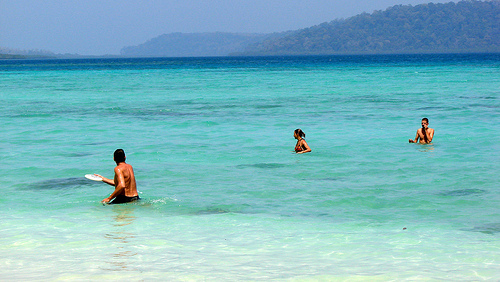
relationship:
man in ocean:
[85, 149, 139, 207] [180, 55, 266, 146]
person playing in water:
[293, 128, 312, 153] [4, 61, 477, 256]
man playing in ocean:
[85, 149, 139, 207] [0, 64, 500, 280]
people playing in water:
[98, 106, 455, 208] [323, 65, 372, 98]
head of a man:
[114, 147, 125, 165] [410, 116, 432, 142]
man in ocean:
[85, 149, 139, 207] [1, 52, 498, 280]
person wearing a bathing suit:
[293, 128, 312, 153] [292, 137, 305, 152]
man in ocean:
[85, 149, 139, 207] [0, 64, 500, 280]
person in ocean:
[290, 125, 312, 154] [0, 64, 500, 280]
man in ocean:
[409, 117, 435, 145] [0, 64, 500, 280]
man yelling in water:
[398, 108, 439, 152] [319, 141, 483, 209]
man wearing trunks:
[79, 142, 144, 208] [112, 192, 135, 208]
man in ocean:
[79, 142, 144, 208] [0, 64, 500, 280]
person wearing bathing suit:
[293, 128, 312, 153] [295, 138, 306, 152]